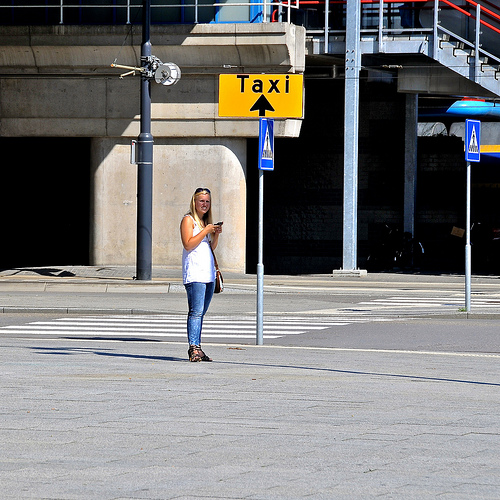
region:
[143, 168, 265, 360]
ladyis standing in the open air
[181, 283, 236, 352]
pants are blue in color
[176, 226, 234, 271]
blouse is white in color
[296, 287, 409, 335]
the road has white lins across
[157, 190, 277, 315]
lady is holding a phone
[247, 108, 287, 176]
poster is blue in color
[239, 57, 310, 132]
taxi is yellow in color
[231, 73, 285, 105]
words are written in black color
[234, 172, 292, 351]
the post is metallic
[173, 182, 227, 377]
woman standing on the sidewalk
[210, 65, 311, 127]
black and yellow taxi sign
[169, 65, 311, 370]
woman waiting for a taxi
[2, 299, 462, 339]
part of a crosswalk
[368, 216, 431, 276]
bicycle leaning against a pole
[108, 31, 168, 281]
part of a light pole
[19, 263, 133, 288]
part of a sidewalk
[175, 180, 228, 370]
woman wearing blue jeans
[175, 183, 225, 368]
woman wearing white shirt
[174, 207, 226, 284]
woman wearing a white shirt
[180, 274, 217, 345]
woman wearing blue jeans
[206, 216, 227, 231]
woman holding a cellphone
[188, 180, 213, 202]
sunglasses on a woman head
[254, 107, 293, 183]
blue sign on a pole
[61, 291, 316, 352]
white paint on the ground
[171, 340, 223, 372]
woman wearing brown shoes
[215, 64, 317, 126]
Taxi sign on the pole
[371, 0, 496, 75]
stairs leading to the building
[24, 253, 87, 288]
shadow of a pole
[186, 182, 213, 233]
woman has blonde hair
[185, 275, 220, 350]
woman has blue pants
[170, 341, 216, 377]
woman has brown shoes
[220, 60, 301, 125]
black and yellow sign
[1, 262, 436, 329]
white crosswalk on road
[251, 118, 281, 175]
blue and white sign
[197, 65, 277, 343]
signs on metal pole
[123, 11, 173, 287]
tall dark grey pole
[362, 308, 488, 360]
road is light grey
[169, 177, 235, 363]
this is a lady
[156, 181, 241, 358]
the lady is standing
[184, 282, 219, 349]
these arenthelegs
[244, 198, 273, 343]
this is a pole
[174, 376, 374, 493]
this is the pavement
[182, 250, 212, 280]
this is a blouse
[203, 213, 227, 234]
she is using a cell phone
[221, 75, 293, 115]
the post is yellow in color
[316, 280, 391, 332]
this is a zebra crossing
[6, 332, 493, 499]
The concrete sidewalk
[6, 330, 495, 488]
A concrete sidewalk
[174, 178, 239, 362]
The woman standing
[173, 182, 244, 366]
A woman standing on the sidewalk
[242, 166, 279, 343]
The metal pole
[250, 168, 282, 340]
A metal pole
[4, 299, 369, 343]
The thick white lines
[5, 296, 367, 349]
A set of thick white lines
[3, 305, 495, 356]
The black paved road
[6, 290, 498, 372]
A black paved road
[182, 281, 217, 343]
a woman's blue jean pants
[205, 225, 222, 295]
a woman's handbag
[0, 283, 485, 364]
white pedestrian street marking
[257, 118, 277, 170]
a blue and white street sign